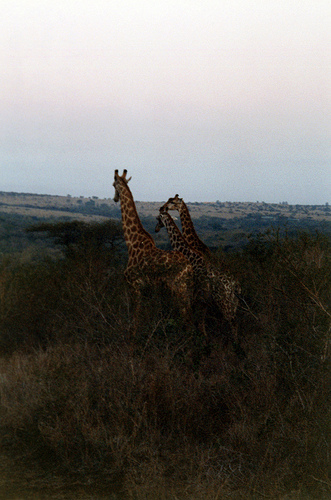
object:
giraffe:
[112, 169, 195, 344]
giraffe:
[154, 207, 242, 351]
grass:
[0, 238, 330, 496]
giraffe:
[159, 194, 210, 254]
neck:
[117, 189, 154, 258]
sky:
[4, 0, 175, 127]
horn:
[114, 169, 122, 183]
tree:
[32, 221, 145, 255]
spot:
[136, 236, 144, 246]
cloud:
[16, 83, 205, 153]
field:
[4, 190, 330, 235]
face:
[111, 179, 118, 200]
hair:
[127, 186, 156, 248]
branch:
[103, 234, 116, 250]